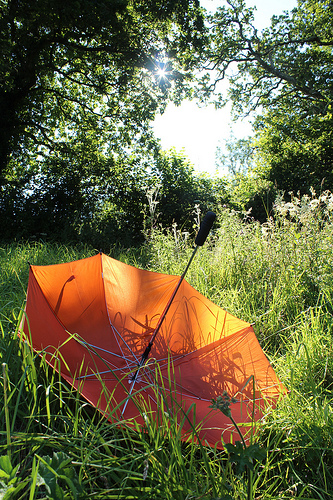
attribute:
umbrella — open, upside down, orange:
[22, 211, 287, 456]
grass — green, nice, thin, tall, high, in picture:
[0, 236, 331, 499]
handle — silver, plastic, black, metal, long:
[128, 211, 217, 384]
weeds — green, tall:
[262, 189, 332, 242]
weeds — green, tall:
[168, 203, 201, 249]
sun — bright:
[156, 68, 169, 81]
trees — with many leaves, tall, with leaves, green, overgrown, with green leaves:
[2, 0, 212, 244]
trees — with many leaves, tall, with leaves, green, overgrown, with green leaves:
[201, 0, 332, 199]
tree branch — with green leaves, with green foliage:
[202, 1, 326, 101]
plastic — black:
[142, 342, 152, 361]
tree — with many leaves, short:
[23, 173, 89, 245]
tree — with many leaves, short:
[89, 185, 150, 250]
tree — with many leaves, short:
[155, 151, 220, 245]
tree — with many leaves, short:
[234, 179, 276, 222]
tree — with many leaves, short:
[259, 133, 331, 194]